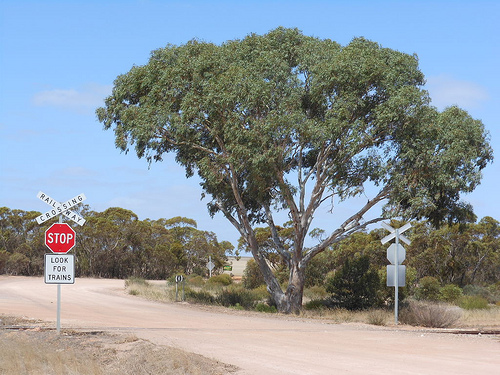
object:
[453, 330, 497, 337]
shadow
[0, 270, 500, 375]
ground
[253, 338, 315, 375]
street dirt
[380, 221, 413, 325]
signs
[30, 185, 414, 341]
railway crossing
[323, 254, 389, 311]
bush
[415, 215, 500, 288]
bush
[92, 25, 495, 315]
tree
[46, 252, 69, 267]
look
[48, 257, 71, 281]
black lettering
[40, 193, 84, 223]
black lettering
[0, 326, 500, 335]
railroad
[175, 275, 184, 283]
sign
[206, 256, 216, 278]
sign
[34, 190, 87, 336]
sign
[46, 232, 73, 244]
letters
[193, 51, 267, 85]
foliage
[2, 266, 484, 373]
road